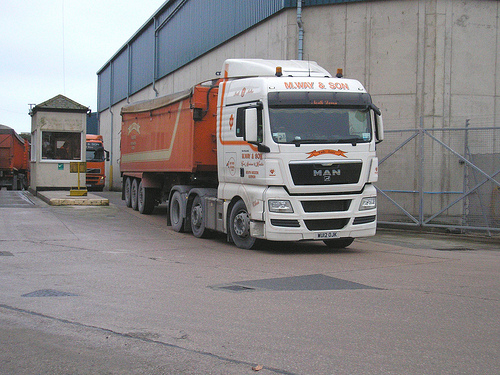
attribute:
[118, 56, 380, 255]
truck — here, white, orange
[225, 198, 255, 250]
front tire — gray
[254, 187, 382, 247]
grill — black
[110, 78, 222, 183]
container — orange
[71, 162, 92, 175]
sign — yellow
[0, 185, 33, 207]
ramp — here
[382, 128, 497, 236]
gate — silver, metal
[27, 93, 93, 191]
shelter — small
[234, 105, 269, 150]
side mirror — here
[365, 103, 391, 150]
right mirror — here